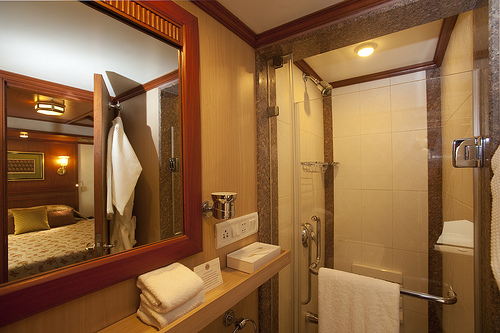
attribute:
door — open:
[86, 73, 116, 255]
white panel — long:
[214, 210, 259, 250]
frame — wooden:
[182, 16, 204, 254]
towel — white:
[301, 253, 418, 331]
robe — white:
[105, 110, 155, 261]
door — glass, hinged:
[284, 61, 491, 331]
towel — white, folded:
[138, 260, 207, 313]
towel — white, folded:
[137, 292, 207, 332]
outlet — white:
[212, 206, 260, 248]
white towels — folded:
[136, 257, 202, 299]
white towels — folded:
[130, 288, 215, 320]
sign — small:
[194, 255, 224, 290]